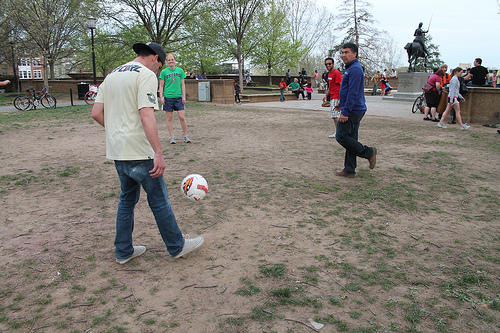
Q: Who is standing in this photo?
A: Men.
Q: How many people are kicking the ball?
A: Four.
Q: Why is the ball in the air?
A: Because the man is kicking it.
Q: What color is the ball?
A: Red and white.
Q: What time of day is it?
A: Daytime.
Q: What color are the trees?
A: Green.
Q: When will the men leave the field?
A: After they finish playing with the ball.